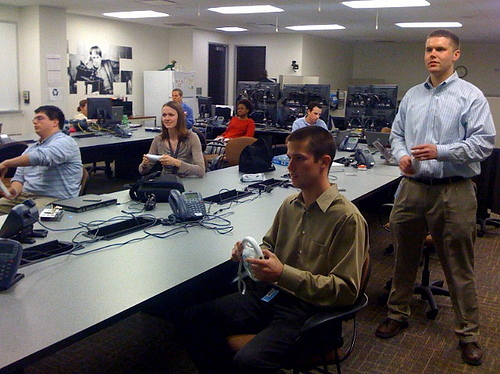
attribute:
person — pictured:
[181, 97, 366, 372]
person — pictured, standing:
[374, 35, 496, 362]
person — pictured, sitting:
[138, 102, 205, 175]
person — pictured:
[0, 105, 85, 201]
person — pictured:
[206, 100, 253, 165]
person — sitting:
[9, 105, 84, 201]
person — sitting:
[296, 100, 331, 136]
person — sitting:
[1, 95, 83, 204]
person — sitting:
[138, 96, 213, 180]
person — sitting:
[168, 84, 196, 129]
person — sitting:
[231, 116, 375, 365]